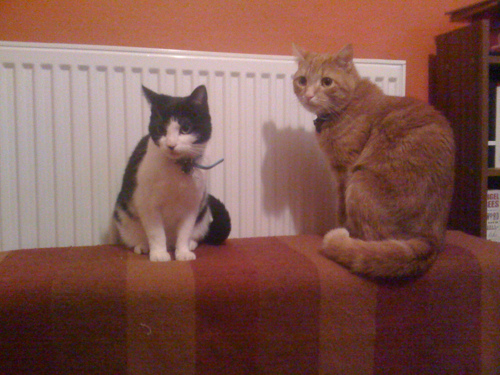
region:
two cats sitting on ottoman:
[108, 43, 442, 286]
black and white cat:
[90, 87, 229, 262]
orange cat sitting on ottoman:
[284, 48, 461, 278]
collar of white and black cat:
[169, 150, 225, 179]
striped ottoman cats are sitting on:
[14, 235, 486, 374]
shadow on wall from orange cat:
[255, 125, 334, 232]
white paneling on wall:
[3, 47, 401, 247]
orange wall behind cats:
[8, 5, 448, 176]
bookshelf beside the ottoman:
[427, 3, 499, 233]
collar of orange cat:
[303, 110, 330, 132]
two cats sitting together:
[92, 45, 463, 280]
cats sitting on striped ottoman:
[6, 51, 491, 364]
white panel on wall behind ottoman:
[7, 38, 412, 243]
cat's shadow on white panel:
[255, 106, 340, 231]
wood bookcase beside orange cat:
[431, 8, 498, 233]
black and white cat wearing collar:
[92, 81, 235, 259]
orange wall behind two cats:
[7, 4, 444, 210]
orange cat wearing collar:
[285, 40, 450, 282]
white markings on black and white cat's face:
[155, 115, 207, 162]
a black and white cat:
[97, 71, 249, 247]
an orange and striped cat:
[277, 32, 438, 275]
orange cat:
[282, 38, 459, 290]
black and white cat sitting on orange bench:
[106, 78, 236, 274]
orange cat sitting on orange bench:
[275, 31, 460, 287]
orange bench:
[3, 224, 499, 371]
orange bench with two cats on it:
[5, 228, 495, 372]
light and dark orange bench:
[0, 222, 495, 372]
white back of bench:
[0, 37, 407, 254]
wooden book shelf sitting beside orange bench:
[420, 17, 497, 238]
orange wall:
[3, 2, 480, 229]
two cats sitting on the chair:
[110, 40, 457, 280]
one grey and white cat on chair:
[110, 80, 230, 260]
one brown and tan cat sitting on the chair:
[285, 40, 455, 280]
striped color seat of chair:
[0, 226, 497, 371]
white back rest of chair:
[3, 42, 400, 249]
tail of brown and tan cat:
[320, 228, 440, 283]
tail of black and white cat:
[207, 192, 232, 248]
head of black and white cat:
[139, 84, 214, 160]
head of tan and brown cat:
[284, 40, 361, 116]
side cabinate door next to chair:
[433, 32, 497, 236]